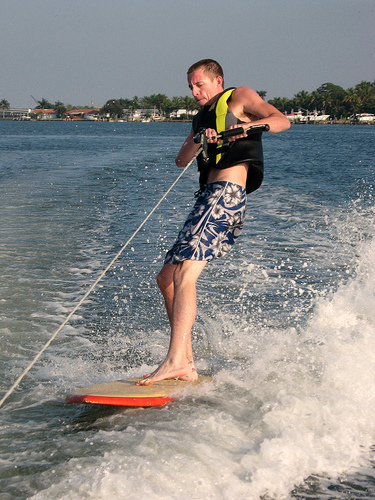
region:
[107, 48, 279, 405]
man water skiing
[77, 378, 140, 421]
brown and orange board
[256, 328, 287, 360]
white and blue waves in water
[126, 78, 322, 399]
a man on a surfboard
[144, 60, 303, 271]
a man surfing in the water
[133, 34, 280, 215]
a man holding onto the rope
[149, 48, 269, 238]
a man wearing lifejacket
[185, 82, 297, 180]
a yellow black and silver life jacket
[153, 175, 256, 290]
a man wearing swim trunks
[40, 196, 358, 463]
a body of water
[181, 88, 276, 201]
the life jacket is black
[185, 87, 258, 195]
the life jacket is black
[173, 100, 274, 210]
the life jacket is black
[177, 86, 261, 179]
the life jacket is black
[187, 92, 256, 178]
the life jacket is black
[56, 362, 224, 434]
the board is orange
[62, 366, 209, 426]
the board is orange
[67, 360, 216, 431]
the board is orange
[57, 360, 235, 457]
the board is orange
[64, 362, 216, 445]
the board is orange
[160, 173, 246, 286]
man wearing blue shorts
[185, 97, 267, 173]
man wearing a life vest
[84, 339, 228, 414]
man on a surfboard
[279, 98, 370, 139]
boats at the waters edge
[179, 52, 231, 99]
man with short hair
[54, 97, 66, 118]
trees at the water edge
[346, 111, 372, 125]
boat at the dock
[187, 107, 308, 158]
man being pulled by a boat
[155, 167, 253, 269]
man wearing swimming trunks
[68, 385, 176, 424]
surfboard in the water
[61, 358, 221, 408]
a surfboard with orange color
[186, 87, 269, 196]
a yellow and black life jacket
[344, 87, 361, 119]
a palm tree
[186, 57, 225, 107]
the head of a man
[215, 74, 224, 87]
ear of a man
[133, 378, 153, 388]
toes of a man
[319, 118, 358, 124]
a wooden dock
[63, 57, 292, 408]
a man using a surfboard and holding onto a rope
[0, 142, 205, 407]
a slim rope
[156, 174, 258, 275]
skier is wearing floral print swim shorts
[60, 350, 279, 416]
wake board is gliding through the water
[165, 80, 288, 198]
Person is wearing a lifevest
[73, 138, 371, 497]
Skier is making a wake with his board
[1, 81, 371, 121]
green trees on horizon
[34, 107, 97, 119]
red roofs on buildings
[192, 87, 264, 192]
black vest with yellow stripe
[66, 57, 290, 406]
man standing on surfboard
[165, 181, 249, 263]
swim trunks with flower print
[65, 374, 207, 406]
yellow and orange surfboard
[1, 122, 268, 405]
hands holding rods attached to rope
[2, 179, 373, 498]
white caps of splashed water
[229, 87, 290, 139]
bent elbow of man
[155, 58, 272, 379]
a man standing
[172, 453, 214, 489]
the water is white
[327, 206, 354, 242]
splash of water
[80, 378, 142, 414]
a surfboard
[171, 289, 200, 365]
the mans legs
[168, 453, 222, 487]
the ocean water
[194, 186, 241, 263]
man is wearing shorts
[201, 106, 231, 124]
man is wearing a vest